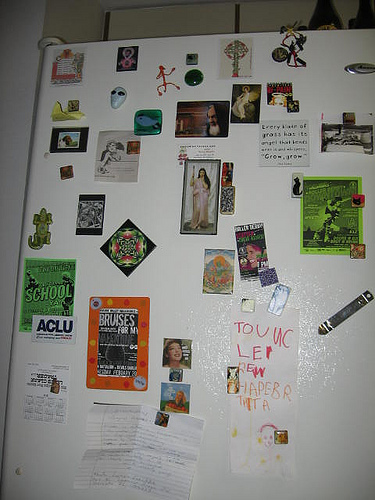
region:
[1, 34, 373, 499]
white refrigerator door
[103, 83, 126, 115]
green alien magnet with big black eyes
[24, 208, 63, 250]
green lizard refrigerator magnet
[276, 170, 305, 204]
square black cat magnet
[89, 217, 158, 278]
pink, white, and green mandala magnet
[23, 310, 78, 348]
white ACLU magnet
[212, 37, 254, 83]
intricate pink and green celtic cross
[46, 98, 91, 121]
torn piece of yellow paper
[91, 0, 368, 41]
white cabinetry above refrigerator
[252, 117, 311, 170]
square white inspirational quote magnet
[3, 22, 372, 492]
A refrigerator door with magnets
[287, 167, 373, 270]
A green flyer held up by magnets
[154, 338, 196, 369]
A small picture of a woman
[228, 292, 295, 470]
A picture drawn by a child held up by magnets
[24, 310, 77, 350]
A magnet that says ACLU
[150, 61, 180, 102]
A orange stick figure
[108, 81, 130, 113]
A white alien head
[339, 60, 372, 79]
A brand label on a refrigerator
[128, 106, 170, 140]
A green and blue refrigerator magnate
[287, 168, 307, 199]
A picture of a black cat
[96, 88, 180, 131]
Magnets on front of the fridge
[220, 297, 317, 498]
A note written by a child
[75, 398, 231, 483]
School work on fridge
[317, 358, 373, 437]
The fridge is white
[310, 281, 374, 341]
Can opener on front of fridge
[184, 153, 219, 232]
Picture of a woman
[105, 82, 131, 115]
Alien magnet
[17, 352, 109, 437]
Calendar on front of fridge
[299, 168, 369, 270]
Green flyer on the front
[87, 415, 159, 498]
Notebook paper with writing on it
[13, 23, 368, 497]
White refrigerator door personalized with magnets and notes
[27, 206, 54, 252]
Green salamandar magnet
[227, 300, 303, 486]
Child's drawing stuck to a fridge door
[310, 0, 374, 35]
Two bottles on top of a refrigerator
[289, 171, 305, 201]
Magnet with a black cat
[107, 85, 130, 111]
Alien face magnet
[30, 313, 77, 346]
ACLU sticker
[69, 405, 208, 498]
A child's school work written on white lined paper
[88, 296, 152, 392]
An orange magnetic frame with decorative dots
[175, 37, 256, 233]
A grouping of religious themed magnets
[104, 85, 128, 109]
An alien magnet on a refridgerator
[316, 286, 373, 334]
A crayon in black as a magnet on a refridgerator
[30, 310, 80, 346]
American civil liberties union magnet on a refridgerator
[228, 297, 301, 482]
Homework held on the refridgerator with magnets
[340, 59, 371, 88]
Logo decal for refridgerator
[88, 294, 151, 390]
Magnet holding bruises for my valentine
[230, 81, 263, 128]
A magnet of an angel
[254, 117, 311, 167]
Every blade of grass magnet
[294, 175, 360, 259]
A notice printed on yellow paper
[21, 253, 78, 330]
A notice printed on green paper